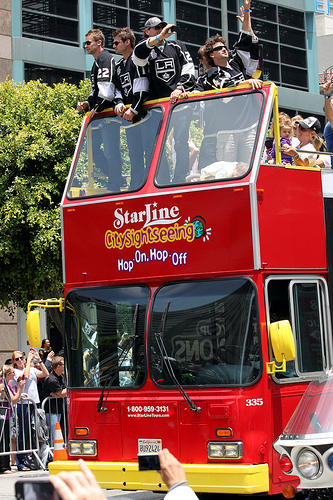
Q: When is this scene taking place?
A: Day time.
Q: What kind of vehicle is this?
A: Bus.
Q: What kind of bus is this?
A: Double decker bus.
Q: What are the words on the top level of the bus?
A: Starline city sightseeing. Hop On Hop Off.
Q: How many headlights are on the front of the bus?
A: Two.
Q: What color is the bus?
A: Red and white.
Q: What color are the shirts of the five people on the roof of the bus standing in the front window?
A: Black and white.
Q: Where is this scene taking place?
A: At a parade.